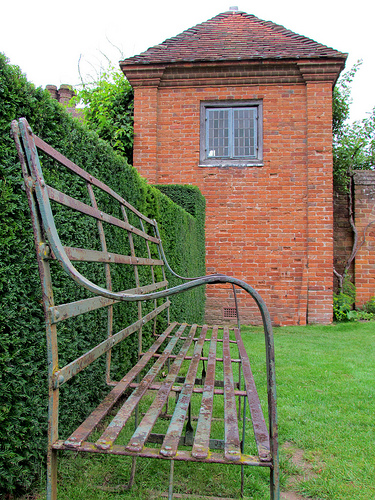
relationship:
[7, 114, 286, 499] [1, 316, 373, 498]
bench on grass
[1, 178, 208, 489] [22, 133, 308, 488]
hedge behind bench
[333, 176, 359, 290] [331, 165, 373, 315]
wine on brick wall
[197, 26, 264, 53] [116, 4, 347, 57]
red tile on roof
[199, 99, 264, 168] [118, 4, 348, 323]
window in building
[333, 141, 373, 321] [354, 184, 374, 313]
tree next to wall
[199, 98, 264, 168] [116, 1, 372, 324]
window on building